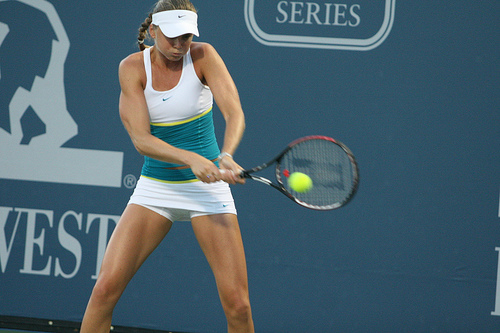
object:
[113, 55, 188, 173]
arms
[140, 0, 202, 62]
head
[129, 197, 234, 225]
shorts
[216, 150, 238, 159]
bracelet/watch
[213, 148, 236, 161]
wrist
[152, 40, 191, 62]
visor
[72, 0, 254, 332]
woman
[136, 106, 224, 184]
turquoise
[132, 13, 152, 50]
braid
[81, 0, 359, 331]
she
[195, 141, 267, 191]
hard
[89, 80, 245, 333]
tennis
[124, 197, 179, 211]
edge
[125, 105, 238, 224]
dress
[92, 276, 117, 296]
knees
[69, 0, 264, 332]
player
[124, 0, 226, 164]
woman wearing top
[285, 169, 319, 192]
tennis ball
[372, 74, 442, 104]
blue wall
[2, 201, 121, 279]
white writing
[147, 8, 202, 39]
white visor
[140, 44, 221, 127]
white tank top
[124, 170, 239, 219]
white skirt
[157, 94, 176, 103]
green swoosh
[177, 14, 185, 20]
black swoosh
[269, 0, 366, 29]
white lettering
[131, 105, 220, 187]
middle of shirt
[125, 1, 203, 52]
woman's hair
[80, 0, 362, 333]
playing tennis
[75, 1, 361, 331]
swinging racket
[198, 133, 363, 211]
hitting the ball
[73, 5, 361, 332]
wearing a outfit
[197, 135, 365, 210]
racket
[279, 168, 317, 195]
ball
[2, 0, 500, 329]
background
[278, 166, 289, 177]
red spot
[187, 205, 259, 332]
muscular legs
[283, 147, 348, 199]
clear strings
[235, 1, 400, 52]
white logo